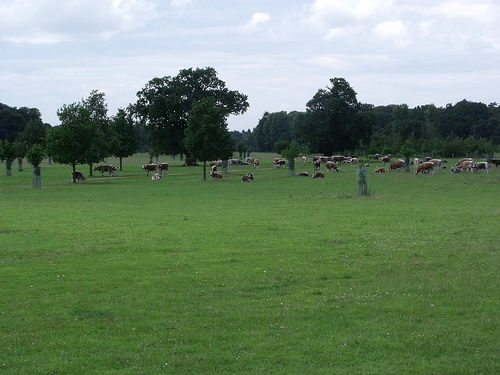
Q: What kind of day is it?
A: Cloudy.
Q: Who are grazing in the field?
A: Animals.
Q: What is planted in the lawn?
A: Trees.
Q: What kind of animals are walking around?
A: Cows.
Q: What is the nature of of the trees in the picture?
A: Tall.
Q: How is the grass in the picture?
A: Manicured.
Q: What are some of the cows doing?
A: Resting.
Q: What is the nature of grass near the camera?
A: Green and muddy.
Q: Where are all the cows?
A: In a field.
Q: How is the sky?
A: Cloudy.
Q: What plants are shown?
A: Trees.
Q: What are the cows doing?
A: Grazing.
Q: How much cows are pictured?
A: A herd.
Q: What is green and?
A: Grass.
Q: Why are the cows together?
A: They are a herd.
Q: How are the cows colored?
A: Brown and white.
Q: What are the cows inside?
A: A field.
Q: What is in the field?
A: Animals.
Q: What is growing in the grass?
A: Trees.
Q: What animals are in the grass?
A: Cows.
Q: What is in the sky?
A: Clouds.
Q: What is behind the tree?
A: Cows.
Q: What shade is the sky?
A: Blue.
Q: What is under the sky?
A: The trees.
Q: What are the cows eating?
A: Grass.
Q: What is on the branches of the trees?
A: Leaves.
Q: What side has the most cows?
A: The right side.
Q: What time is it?
A: Afternoon.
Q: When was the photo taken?
A: During the daytime.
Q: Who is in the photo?
A: No people.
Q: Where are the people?
A: None in photo.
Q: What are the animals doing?
A: Standing and laying.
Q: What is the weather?
A: Cloudy.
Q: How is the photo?
A: Clear.